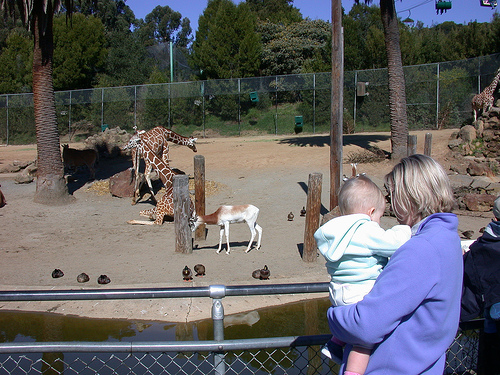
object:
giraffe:
[120, 137, 198, 228]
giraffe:
[130, 124, 198, 204]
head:
[181, 136, 196, 154]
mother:
[324, 152, 462, 374]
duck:
[96, 270, 111, 284]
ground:
[0, 128, 473, 314]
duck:
[74, 272, 89, 283]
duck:
[49, 266, 64, 279]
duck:
[250, 264, 272, 282]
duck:
[180, 264, 195, 281]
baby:
[311, 169, 412, 374]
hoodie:
[312, 208, 411, 285]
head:
[334, 176, 385, 227]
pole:
[434, 59, 442, 127]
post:
[329, 1, 344, 210]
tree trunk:
[22, 0, 74, 205]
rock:
[81, 124, 135, 151]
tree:
[88, 74, 133, 130]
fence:
[0, 58, 497, 149]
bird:
[286, 212, 296, 223]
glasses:
[382, 193, 404, 204]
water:
[0, 295, 382, 374]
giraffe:
[467, 58, 499, 124]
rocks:
[460, 194, 499, 212]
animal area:
[0, 70, 499, 287]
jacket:
[325, 201, 480, 374]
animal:
[119, 135, 199, 227]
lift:
[430, 0, 453, 17]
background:
[0, 0, 498, 375]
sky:
[126, 1, 489, 55]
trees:
[140, 6, 195, 45]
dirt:
[0, 201, 152, 255]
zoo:
[0, 0, 499, 374]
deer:
[187, 203, 264, 254]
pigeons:
[284, 209, 293, 221]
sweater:
[324, 213, 462, 375]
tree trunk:
[171, 175, 192, 253]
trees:
[341, 107, 354, 135]